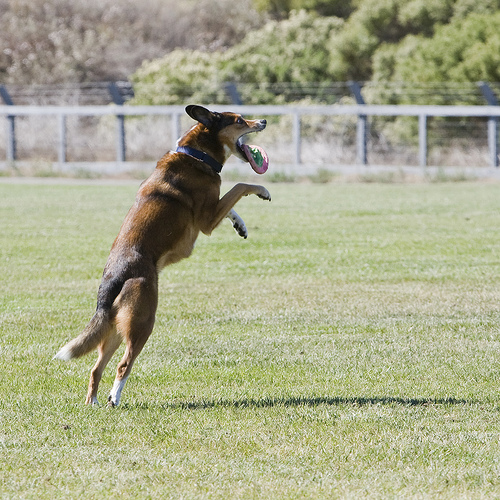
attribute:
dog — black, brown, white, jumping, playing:
[57, 102, 272, 406]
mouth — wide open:
[238, 125, 273, 173]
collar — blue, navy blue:
[179, 141, 223, 171]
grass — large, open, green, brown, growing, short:
[2, 172, 499, 500]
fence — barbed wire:
[1, 80, 498, 169]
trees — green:
[136, 11, 500, 156]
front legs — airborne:
[205, 179, 274, 239]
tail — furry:
[57, 290, 111, 368]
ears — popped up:
[181, 96, 213, 122]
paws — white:
[234, 180, 270, 242]